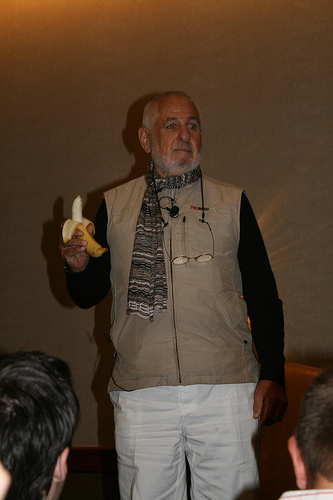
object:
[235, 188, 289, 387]
slleves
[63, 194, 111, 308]
slleves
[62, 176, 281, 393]
shirt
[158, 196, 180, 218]
microphone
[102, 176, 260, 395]
jacket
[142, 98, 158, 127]
hair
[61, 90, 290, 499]
man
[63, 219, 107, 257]
peel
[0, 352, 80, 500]
head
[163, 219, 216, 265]
glasses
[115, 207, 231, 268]
chest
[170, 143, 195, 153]
moustache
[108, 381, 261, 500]
pants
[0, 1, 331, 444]
wall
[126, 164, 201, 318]
scarf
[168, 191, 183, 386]
zipper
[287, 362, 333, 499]
head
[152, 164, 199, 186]
neck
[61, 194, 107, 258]
banana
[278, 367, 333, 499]
man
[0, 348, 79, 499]
man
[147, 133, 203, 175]
facial hair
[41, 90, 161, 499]
shadow